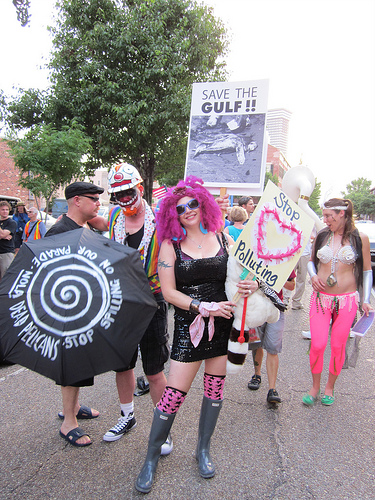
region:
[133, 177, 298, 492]
a demonstrator in disguise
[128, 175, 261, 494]
a woman with purple in her hair and socks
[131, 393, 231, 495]
a pair of gray boots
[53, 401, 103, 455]
a pair of sandals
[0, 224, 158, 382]
an umbrella objecting to dead pelicans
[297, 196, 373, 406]
a woman in pink pants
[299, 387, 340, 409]
a pair of green shoes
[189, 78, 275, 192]
a sign that includes a photo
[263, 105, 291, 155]
a tall building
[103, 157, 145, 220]
a man with a helmet and a mask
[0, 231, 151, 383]
large black umbrella with words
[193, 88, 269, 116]
wording on protest poster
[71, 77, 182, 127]
leaves from the tree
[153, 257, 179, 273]
tattoo on woman's arm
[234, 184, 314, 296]
ladies hold holding protest sign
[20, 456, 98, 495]
a crack on the street pavement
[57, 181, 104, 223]
man wearing glasses and black cap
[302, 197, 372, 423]
female protester with pink pants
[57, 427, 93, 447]
black sandals on man's foot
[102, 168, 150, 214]
man in hat with face paint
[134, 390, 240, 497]
grey rain boots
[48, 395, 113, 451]
dark blue sandals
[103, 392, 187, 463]
black converse shoes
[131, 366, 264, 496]
high pink and black socks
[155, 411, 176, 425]
label on the grey boots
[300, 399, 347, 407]
green slippers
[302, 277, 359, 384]
pink capris pants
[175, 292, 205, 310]
dark and thick bracelet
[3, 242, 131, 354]
white writing and design on the black umbrella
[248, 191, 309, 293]
black writing on the poster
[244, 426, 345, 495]
cement covered road way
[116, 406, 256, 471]
gray hunter rainboots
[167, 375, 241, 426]
black and pink knee socks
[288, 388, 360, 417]
green Chinese slippers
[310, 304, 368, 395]
hot pink running leggings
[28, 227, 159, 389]
black and white swirl umbrella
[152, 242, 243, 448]
black sequined tight dress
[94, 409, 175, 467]
black and white converse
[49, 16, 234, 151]
large green planted treet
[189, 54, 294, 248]
black and white protest sign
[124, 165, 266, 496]
lady wearing black sequin dress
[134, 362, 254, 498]
lady wearing grey boots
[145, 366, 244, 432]
lady wearing pink and black socks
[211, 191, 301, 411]
lady carrying a stuffed animal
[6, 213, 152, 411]
black and white umbrella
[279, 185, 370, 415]
lady wearing pink pants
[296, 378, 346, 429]
lady wearing green shoes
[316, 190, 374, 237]
lady wearing white head band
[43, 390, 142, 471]
man wearing black flip flops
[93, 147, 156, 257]
man wearing helmet and mask